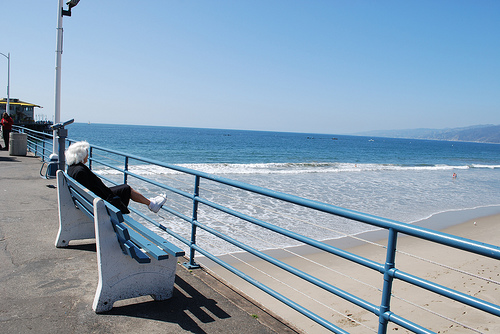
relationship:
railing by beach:
[5, 121, 495, 331] [128, 173, 499, 281]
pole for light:
[46, 1, 81, 186] [63, 1, 80, 16]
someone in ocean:
[451, 169, 457, 180] [95, 126, 494, 189]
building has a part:
[1, 97, 43, 125] [19, 108, 29, 117]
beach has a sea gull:
[128, 173, 499, 281] [473, 220, 477, 228]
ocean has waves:
[95, 126, 494, 189] [269, 159, 433, 176]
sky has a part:
[85, 3, 495, 123] [19, 108, 29, 117]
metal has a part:
[54, 45, 62, 164] [55, 114, 58, 125]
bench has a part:
[55, 169, 186, 309] [143, 230, 164, 242]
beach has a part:
[128, 173, 499, 281] [19, 108, 29, 117]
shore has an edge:
[400, 198, 498, 222] [492, 192, 499, 238]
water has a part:
[394, 190, 498, 222] [442, 204, 457, 212]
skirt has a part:
[110, 181, 131, 210] [117, 192, 123, 197]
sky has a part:
[85, 3, 495, 123] [193, 48, 231, 80]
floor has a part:
[5, 182, 54, 332] [14, 263, 44, 294]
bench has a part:
[55, 169, 186, 309] [89, 206, 100, 218]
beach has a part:
[128, 173, 499, 281] [350, 190, 401, 209]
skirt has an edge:
[110, 181, 131, 210] [127, 190, 131, 207]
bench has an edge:
[55, 169, 186, 309] [132, 216, 181, 254]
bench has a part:
[55, 169, 186, 309] [129, 223, 142, 237]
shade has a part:
[2, 155, 21, 164] [6, 159, 14, 162]